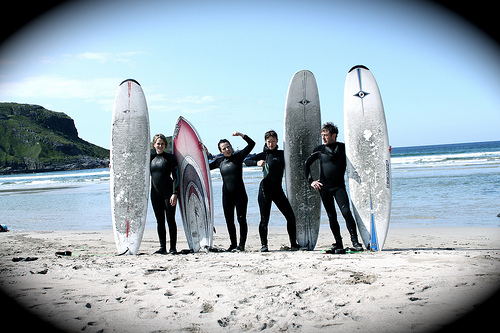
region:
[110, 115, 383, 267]
four adults posing with surfboards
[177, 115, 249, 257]
woman in black wet suit holding surfboard with red designs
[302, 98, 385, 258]
man posing with surfboard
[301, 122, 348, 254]
man looking to his right holding surfboard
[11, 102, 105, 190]
green hills in the brackground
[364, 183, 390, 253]
surfboard with blue arrow on bottom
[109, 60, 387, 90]
two surfboards have black at the top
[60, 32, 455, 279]
people standing on beach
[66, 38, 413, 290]
people holding surfboards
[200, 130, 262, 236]
woman wearing a wet suit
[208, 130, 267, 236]
the women's wet suit is black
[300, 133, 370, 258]
man wearing a wet suit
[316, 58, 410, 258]
blue and white surfboard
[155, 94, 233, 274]
pink and white surfboard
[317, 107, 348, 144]
man with dark hair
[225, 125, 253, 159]
woman has arm up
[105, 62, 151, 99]
blue tip on surfboard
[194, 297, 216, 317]
sand pit on beach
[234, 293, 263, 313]
sand pit on beach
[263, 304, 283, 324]
sand pit on beach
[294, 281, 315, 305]
sand pit on beach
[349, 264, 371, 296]
sand pit on beach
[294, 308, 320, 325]
sand pit on beach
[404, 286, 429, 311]
sand pit on beach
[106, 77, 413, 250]
people standing in the sand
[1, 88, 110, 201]
mountain next to the water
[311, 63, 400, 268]
person holding a surfboard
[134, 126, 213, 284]
person wearing a wet suit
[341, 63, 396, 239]
the surfboard is white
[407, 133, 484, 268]
the water is calm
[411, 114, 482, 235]
the water is blue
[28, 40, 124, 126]
clouds in the sky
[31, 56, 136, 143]
the clouds are white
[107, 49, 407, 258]
group of people on the beach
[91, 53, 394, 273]
group of people holding surf boards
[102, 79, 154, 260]
white long board being held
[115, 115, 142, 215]
wax on front of board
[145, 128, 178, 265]
woman in a wetsuit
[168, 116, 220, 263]
red and white surf board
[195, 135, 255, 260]
woman in a wet suit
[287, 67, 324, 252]
long white board being held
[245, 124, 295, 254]
woman wearing a wet suit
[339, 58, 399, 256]
white surf board being held